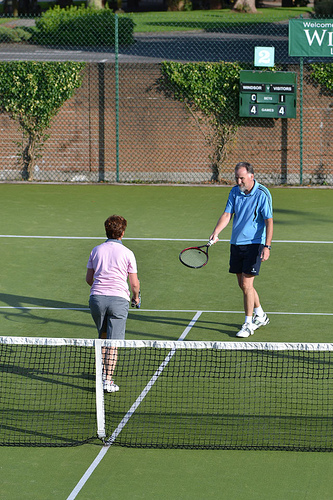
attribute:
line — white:
[91, 337, 108, 437]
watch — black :
[261, 243, 272, 251]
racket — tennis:
[178, 235, 219, 267]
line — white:
[134, 219, 214, 251]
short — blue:
[229, 245, 262, 268]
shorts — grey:
[84, 293, 131, 340]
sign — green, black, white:
[236, 66, 302, 132]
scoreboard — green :
[238, 68, 298, 117]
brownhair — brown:
[102, 210, 130, 241]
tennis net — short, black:
[2, 333, 327, 427]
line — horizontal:
[270, 306, 328, 322]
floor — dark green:
[140, 175, 183, 262]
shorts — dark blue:
[228, 243, 261, 277]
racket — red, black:
[178, 238, 219, 269]